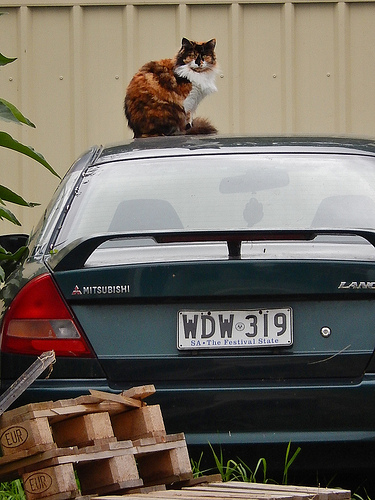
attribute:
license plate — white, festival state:
[178, 294, 300, 355]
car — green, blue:
[64, 153, 367, 400]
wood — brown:
[82, 389, 164, 491]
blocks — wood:
[26, 406, 122, 488]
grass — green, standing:
[12, 204, 35, 287]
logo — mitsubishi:
[61, 272, 148, 309]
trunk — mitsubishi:
[108, 249, 375, 400]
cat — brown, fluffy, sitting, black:
[134, 38, 229, 150]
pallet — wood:
[98, 438, 207, 485]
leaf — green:
[5, 87, 31, 134]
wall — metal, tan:
[239, 17, 353, 120]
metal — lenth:
[227, 19, 311, 40]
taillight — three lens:
[41, 282, 86, 364]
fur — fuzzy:
[155, 78, 189, 103]